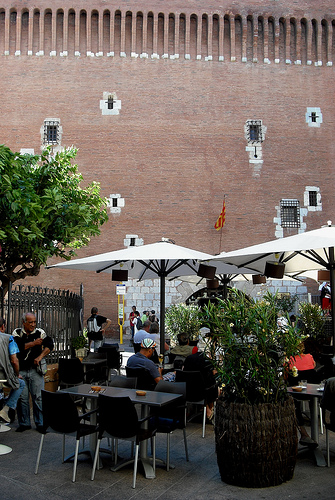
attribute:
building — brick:
[2, 1, 332, 351]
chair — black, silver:
[90, 391, 160, 494]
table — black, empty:
[58, 380, 194, 478]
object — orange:
[280, 351, 318, 374]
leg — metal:
[125, 440, 142, 489]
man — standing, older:
[10, 309, 51, 434]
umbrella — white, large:
[53, 234, 254, 292]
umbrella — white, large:
[199, 221, 334, 274]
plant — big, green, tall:
[168, 280, 323, 403]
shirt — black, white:
[10, 327, 52, 374]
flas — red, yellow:
[208, 197, 234, 236]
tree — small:
[1, 139, 116, 334]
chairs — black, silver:
[27, 385, 158, 491]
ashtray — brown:
[87, 384, 103, 397]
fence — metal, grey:
[1, 276, 93, 361]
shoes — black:
[14, 421, 48, 437]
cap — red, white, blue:
[139, 338, 160, 351]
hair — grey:
[17, 310, 41, 333]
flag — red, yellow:
[211, 198, 231, 236]